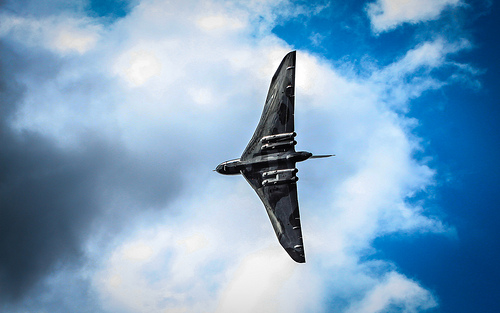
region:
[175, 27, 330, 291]
a jet is in the sky.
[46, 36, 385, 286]
the cloud is white.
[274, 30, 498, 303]
the sky is blue.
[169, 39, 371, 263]
one jet in the sky.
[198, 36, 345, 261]
the jet is grey.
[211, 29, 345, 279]
two wings on the jet.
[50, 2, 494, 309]
the sky is cloudy.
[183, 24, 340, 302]
the wing is a triangle.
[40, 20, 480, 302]
it is day time.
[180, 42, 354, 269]
the jet has a tail.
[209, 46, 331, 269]
Military plane soaring through the sky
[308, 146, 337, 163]
Tail of fighter plane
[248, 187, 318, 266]
Wing on military plane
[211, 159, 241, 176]
Nose of airplane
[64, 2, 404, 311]
Huge white cloud in sky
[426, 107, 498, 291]
Patch of clear blue sky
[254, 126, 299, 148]
Two engines on plane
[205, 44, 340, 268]
Plane is black and gray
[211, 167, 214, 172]
Needle point at tip of nose on plane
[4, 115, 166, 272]
Black storm clouds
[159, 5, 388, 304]
futuristic flying vehicle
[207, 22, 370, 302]
grey space jet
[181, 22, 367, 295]
dark grey space plane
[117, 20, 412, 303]
plane flying below white clouds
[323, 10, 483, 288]
bright blue sky with puffy white clouds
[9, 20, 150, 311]
cumulous and cumulonimbus clouds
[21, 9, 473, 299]
looking up at fighter jet flying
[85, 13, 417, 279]
fighter jet flying in sky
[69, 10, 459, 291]
flight of military jet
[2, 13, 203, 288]
clouds indicating approaching storm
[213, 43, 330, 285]
military airplane in the sky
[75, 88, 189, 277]
thick white clouds covering sky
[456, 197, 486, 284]
dark blue clear area of sky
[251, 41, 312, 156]
wing of airplane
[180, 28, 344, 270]
one military airplane flying in sky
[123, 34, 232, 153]
white clouds behind the airplane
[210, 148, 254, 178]
small front area of airplane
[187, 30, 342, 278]
airplane turned sideways in sky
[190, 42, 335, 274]
grey and black military airplane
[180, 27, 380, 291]
airplane flying through cloudy sky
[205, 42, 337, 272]
Plane in the sky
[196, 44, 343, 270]
Military plane flying in the sky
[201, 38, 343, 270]
Plane is black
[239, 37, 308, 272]
Wings of plane is black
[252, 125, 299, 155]
Engines on right side of plane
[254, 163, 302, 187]
Engines on left side of plane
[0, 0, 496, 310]
Sky is blue with clouds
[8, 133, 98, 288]
Clouds are dark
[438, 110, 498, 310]
Sky is blue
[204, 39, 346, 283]
Plane is in motion